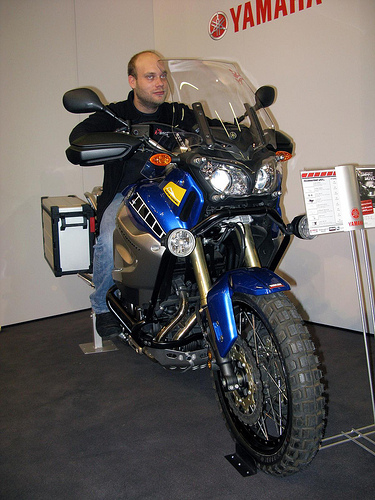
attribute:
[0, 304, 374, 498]
ground — dark grey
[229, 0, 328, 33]
letters — red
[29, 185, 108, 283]
box — white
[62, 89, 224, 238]
jacket — black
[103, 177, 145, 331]
jeans — blue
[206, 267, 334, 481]
wheel — black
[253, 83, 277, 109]
mirror — black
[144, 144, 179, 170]
light — orange, signal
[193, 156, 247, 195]
lights — orange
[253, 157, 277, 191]
lights — orange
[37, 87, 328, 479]
bike — grey, blue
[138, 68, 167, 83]
eyes — open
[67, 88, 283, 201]
jacket — black